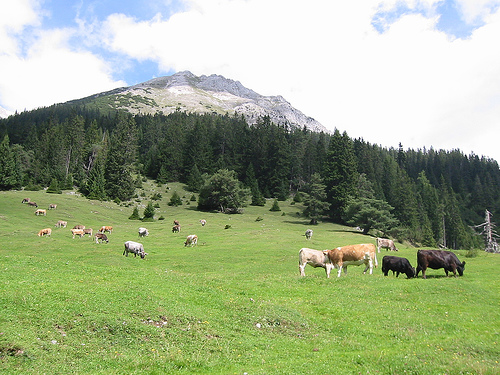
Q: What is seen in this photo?
A: Herd of cattle.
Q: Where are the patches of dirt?
A: In the grass field.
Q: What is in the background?
A: Rocky mountain top.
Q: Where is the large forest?
A: On the hill.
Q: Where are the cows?
A: In a pasture.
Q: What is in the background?
A: Mountains.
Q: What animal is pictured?
A: Cows.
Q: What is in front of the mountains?
A: Tall trees.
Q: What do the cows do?
A: Graze.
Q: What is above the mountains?
A: Blue sky with clouds.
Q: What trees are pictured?
A: Evergreens.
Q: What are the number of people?
A: Zero.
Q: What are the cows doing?
A: Grazing.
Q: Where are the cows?
A: In a field.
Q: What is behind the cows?
A: Trees.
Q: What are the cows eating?
A: Grass.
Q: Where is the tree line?
A: On a mountain.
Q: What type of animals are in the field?
A: Cows.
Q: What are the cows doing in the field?
A: Grazing.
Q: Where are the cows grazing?
A: In the field.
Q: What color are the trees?
A: Green.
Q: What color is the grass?
A: Green.